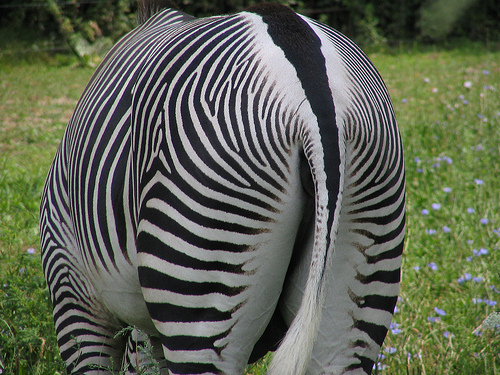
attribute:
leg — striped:
[132, 138, 295, 374]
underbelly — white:
[98, 268, 157, 336]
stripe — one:
[255, 14, 343, 370]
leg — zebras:
[165, 201, 283, 372]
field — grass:
[396, 76, 483, 224]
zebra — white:
[56, 17, 478, 370]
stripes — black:
[91, 47, 211, 175]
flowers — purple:
[413, 70, 496, 360]